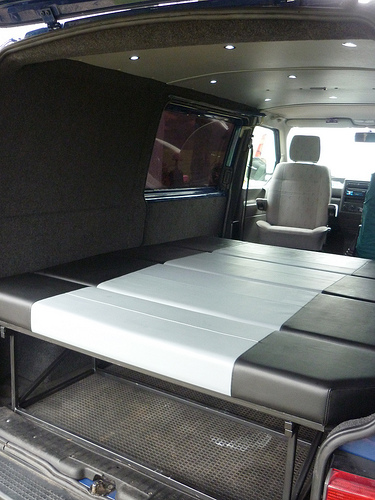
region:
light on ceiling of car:
[134, 54, 140, 61]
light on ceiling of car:
[226, 44, 235, 51]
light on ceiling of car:
[211, 79, 217, 83]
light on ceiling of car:
[342, 42, 357, 47]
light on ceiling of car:
[327, 95, 339, 101]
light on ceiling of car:
[289, 74, 295, 80]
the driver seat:
[254, 138, 333, 244]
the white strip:
[28, 235, 367, 401]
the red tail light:
[323, 464, 374, 494]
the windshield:
[287, 121, 368, 185]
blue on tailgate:
[80, 473, 116, 498]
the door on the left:
[244, 117, 285, 231]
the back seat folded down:
[1, 224, 372, 432]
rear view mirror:
[349, 128, 373, 142]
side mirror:
[246, 156, 272, 183]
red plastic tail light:
[321, 467, 373, 498]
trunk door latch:
[86, 474, 114, 497]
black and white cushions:
[1, 235, 373, 425]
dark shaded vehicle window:
[143, 95, 245, 203]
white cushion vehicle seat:
[255, 132, 340, 250]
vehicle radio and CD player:
[339, 179, 368, 214]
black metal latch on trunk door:
[35, 6, 60, 31]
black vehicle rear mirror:
[352, 130, 373, 143]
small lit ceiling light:
[127, 53, 139, 63]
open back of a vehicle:
[0, 0, 373, 498]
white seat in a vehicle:
[247, 114, 338, 245]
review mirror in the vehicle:
[350, 132, 374, 144]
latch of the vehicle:
[76, 462, 126, 496]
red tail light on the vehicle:
[324, 468, 373, 498]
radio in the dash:
[342, 177, 362, 222]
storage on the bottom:
[66, 408, 250, 480]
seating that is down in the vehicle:
[92, 263, 364, 374]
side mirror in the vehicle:
[140, 128, 232, 197]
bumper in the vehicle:
[2, 422, 97, 499]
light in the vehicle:
[345, 188, 356, 197]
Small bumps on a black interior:
[2, 456, 14, 470]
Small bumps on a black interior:
[11, 458, 19, 472]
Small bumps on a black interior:
[35, 398, 45, 410]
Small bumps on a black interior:
[51, 391, 66, 409]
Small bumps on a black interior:
[60, 382, 85, 398]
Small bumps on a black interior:
[78, 374, 105, 388]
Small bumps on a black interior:
[100, 379, 124, 390]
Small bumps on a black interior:
[115, 383, 128, 397]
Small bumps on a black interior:
[121, 373, 148, 413]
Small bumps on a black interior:
[160, 412, 177, 433]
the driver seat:
[256, 129, 339, 246]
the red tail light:
[317, 463, 371, 497]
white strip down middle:
[26, 238, 369, 396]